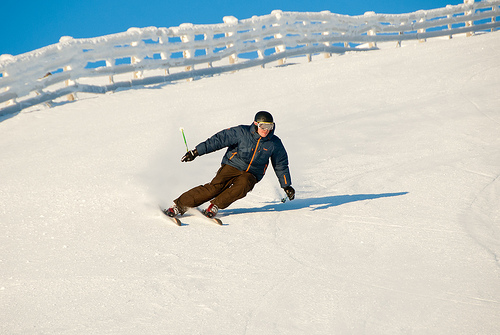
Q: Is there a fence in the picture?
A: Yes, there is a fence.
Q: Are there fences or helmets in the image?
A: Yes, there is a fence.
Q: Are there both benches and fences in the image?
A: No, there is a fence but no benches.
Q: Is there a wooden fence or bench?
A: Yes, there is a wood fence.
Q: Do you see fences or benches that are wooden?
A: Yes, the fence is wooden.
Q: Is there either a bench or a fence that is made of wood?
A: Yes, the fence is made of wood.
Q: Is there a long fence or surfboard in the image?
A: Yes, there is a long fence.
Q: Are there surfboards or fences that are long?
A: Yes, the fence is long.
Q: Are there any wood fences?
A: Yes, there is a fence that is made of wood.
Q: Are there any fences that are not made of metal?
A: Yes, there is a fence that is made of wood.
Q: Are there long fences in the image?
A: Yes, there is a long fence.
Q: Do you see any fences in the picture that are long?
A: Yes, there is a fence that is long.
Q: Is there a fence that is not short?
A: Yes, there is a long fence.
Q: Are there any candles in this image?
A: No, there are no candles.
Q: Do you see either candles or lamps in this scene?
A: No, there are no candles or lamps.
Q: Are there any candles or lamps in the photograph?
A: No, there are no candles or lamps.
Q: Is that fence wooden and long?
A: Yes, the fence is wooden and long.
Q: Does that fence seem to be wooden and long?
A: Yes, the fence is wooden and long.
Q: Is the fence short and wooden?
A: No, the fence is wooden but long.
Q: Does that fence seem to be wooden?
A: Yes, the fence is wooden.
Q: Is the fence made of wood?
A: Yes, the fence is made of wood.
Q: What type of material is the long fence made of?
A: The fence is made of wood.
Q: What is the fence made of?
A: The fence is made of wood.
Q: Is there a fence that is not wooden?
A: No, there is a fence but it is wooden.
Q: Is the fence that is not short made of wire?
A: No, the fence is made of wood.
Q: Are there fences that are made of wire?
A: No, there is a fence but it is made of wood.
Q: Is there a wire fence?
A: No, there is a fence but it is made of wood.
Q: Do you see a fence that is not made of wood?
A: No, there is a fence but it is made of wood.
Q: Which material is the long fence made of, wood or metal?
A: The fence is made of wood.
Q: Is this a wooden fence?
A: Yes, this is a wooden fence.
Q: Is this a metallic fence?
A: No, this is a wooden fence.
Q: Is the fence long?
A: Yes, the fence is long.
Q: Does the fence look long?
A: Yes, the fence is long.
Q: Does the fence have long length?
A: Yes, the fence is long.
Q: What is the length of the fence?
A: The fence is long.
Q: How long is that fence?
A: The fence is long.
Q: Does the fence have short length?
A: No, the fence is long.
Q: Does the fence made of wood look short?
A: No, the fence is long.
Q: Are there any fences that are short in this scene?
A: No, there is a fence but it is long.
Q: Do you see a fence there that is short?
A: No, there is a fence but it is long.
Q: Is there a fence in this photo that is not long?
A: No, there is a fence but it is long.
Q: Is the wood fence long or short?
A: The fence is long.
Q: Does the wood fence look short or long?
A: The fence is long.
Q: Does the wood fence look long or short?
A: The fence is long.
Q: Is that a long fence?
A: Yes, that is a long fence.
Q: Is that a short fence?
A: No, that is a long fence.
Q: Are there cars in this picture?
A: No, there are no cars.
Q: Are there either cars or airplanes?
A: No, there are no cars or airplanes.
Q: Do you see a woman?
A: No, there are no women.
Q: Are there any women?
A: No, there are no women.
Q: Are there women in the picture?
A: No, there are no women.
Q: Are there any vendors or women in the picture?
A: No, there are no women or vendors.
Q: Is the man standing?
A: Yes, the man is standing.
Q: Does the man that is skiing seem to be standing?
A: Yes, the man is standing.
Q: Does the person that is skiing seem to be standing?
A: Yes, the man is standing.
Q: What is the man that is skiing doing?
A: The man is standing.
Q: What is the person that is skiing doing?
A: The man is standing.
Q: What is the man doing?
A: The man is standing.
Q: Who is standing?
A: The man is standing.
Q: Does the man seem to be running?
A: No, the man is standing.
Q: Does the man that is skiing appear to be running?
A: No, the man is standing.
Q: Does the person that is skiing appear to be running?
A: No, the man is standing.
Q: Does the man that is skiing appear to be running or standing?
A: The man is standing.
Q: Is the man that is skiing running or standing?
A: The man is standing.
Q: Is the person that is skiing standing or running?
A: The man is standing.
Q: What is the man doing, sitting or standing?
A: The man is standing.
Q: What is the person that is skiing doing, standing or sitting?
A: The man is standing.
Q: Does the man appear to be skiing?
A: Yes, the man is skiing.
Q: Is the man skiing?
A: Yes, the man is skiing.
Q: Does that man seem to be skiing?
A: Yes, the man is skiing.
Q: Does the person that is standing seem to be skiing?
A: Yes, the man is skiing.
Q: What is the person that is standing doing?
A: The man is skiing.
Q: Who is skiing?
A: The man is skiing.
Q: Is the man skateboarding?
A: No, the man is skiing.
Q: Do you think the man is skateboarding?
A: No, the man is skiing.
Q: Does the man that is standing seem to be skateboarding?
A: No, the man is skiing.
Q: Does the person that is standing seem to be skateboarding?
A: No, the man is skiing.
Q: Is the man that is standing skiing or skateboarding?
A: The man is skiing.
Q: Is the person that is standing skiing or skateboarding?
A: The man is skiing.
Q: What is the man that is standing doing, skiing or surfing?
A: The man is skiing.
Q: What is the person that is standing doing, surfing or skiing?
A: The man is skiing.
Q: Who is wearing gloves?
A: The man is wearing gloves.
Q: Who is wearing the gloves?
A: The man is wearing gloves.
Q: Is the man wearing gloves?
A: Yes, the man is wearing gloves.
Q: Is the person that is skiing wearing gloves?
A: Yes, the man is wearing gloves.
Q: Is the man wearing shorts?
A: No, the man is wearing gloves.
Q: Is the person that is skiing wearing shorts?
A: No, the man is wearing gloves.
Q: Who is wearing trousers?
A: The man is wearing trousers.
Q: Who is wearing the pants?
A: The man is wearing trousers.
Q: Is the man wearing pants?
A: Yes, the man is wearing pants.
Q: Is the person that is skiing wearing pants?
A: Yes, the man is wearing pants.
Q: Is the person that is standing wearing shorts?
A: No, the man is wearing pants.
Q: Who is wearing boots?
A: The man is wearing boots.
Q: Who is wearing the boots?
A: The man is wearing boots.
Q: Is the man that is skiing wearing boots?
A: Yes, the man is wearing boots.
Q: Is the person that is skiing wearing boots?
A: Yes, the man is wearing boots.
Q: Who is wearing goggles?
A: The man is wearing goggles.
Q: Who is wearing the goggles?
A: The man is wearing goggles.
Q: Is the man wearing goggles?
A: Yes, the man is wearing goggles.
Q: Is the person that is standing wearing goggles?
A: Yes, the man is wearing goggles.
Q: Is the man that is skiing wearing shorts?
A: No, the man is wearing goggles.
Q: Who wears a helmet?
A: The man wears a helmet.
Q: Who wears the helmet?
A: The man wears a helmet.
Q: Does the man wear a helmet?
A: Yes, the man wears a helmet.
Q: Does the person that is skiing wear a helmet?
A: Yes, the man wears a helmet.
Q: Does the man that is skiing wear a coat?
A: No, the man wears a helmet.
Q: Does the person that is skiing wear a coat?
A: No, the man wears a helmet.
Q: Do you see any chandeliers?
A: No, there are no chandeliers.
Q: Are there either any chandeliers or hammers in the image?
A: No, there are no chandeliers or hammers.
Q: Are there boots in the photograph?
A: Yes, there are boots.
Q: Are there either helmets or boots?
A: Yes, there are boots.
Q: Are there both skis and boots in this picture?
A: Yes, there are both boots and skis.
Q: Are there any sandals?
A: No, there are no sandals.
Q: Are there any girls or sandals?
A: No, there are no sandals or girls.